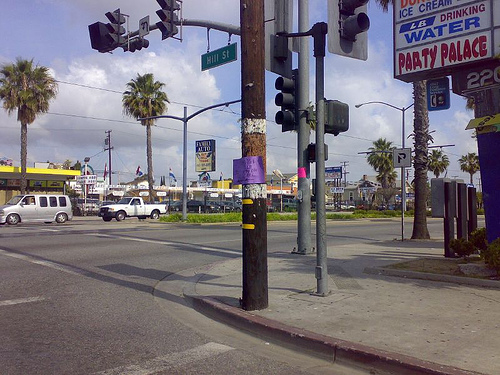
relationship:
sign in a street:
[201, 42, 235, 75] [3, 222, 234, 374]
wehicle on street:
[98, 196, 171, 222] [3, 222, 234, 374]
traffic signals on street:
[89, 3, 194, 53] [3, 222, 234, 374]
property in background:
[183, 173, 228, 203] [6, 163, 229, 191]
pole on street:
[176, 105, 200, 218] [3, 222, 234, 374]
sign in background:
[194, 138, 217, 174] [6, 163, 229, 191]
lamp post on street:
[138, 113, 187, 122] [3, 222, 234, 374]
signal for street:
[275, 68, 299, 138] [3, 222, 234, 374]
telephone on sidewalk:
[428, 178, 454, 255] [204, 312, 439, 363]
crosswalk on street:
[15, 224, 202, 283] [0, 213, 499, 372]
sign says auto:
[194, 138, 217, 174] [198, 147, 213, 152]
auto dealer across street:
[178, 194, 241, 216] [3, 222, 234, 374]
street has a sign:
[3, 222, 234, 374] [138, 15, 151, 39]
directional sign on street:
[138, 15, 151, 39] [3, 222, 234, 374]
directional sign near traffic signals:
[138, 15, 151, 39] [89, 3, 194, 53]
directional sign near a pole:
[138, 15, 151, 39] [176, 105, 200, 218]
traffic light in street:
[155, 0, 178, 42] [3, 222, 234, 374]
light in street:
[275, 68, 299, 138] [3, 222, 234, 374]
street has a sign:
[3, 222, 234, 374] [194, 138, 217, 174]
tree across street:
[124, 74, 168, 194] [3, 222, 234, 374]